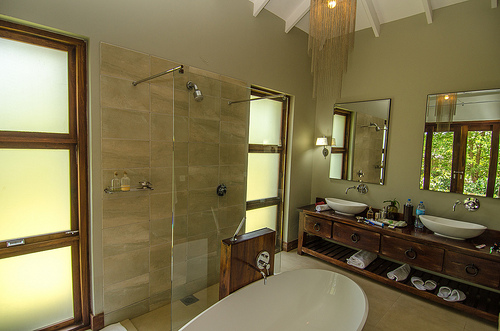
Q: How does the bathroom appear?
A: Neat and tidy.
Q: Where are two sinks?
A: On countertop.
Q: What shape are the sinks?
A: Oval.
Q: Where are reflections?
A: On mirrors.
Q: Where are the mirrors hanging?
A: On the wall.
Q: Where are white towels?
A: On a bottom shelf.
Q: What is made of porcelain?
A: The tub.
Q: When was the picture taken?
A: During the daytime.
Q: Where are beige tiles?
A: On shower wall.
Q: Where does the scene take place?
A: In a bathroom.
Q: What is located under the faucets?
A: Two white sinks.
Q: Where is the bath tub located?
A: On the floor.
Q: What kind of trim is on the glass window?
A: Wood.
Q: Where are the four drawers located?
A: Under the sink basin.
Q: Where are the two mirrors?
A: Above the sink basins.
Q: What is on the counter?
A: Sinks.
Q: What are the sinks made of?
A: Ceramic.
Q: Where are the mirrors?
A: Wall.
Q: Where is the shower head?
A: On the wall.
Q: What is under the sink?
A: Rolled towels.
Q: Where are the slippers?
A: Under the sink.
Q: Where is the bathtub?
A: In the bathroom.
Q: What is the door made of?
A: Glass and wood.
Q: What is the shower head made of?
A: Metal.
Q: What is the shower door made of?
A: Glass.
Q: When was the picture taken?
A: In the daytime.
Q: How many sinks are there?
A: 2.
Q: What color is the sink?
A: White.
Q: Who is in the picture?
A: No one.